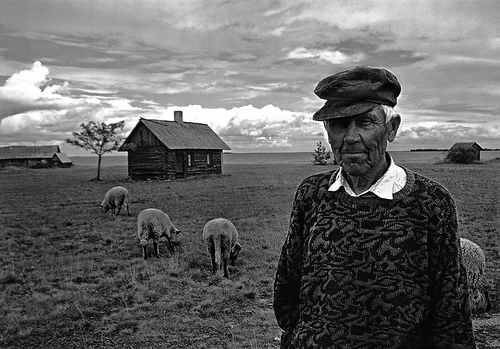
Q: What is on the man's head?
A: Hat.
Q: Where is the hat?
A: On the man's head.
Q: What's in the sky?
A: Clouds.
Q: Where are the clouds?
A: Sky.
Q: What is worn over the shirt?
A: Sweater.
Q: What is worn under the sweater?
A: Shirt.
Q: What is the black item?
A: Sweater.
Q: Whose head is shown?
A: The man.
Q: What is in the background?
A: House.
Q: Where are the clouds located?
A: Sky.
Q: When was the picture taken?
A: Daytime.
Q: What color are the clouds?
A: White.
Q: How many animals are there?
A: Four.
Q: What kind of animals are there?
A: Sheep.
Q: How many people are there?
A: One.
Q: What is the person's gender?
A: Male.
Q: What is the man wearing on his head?
A: A hat.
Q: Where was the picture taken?
A: On the planes.